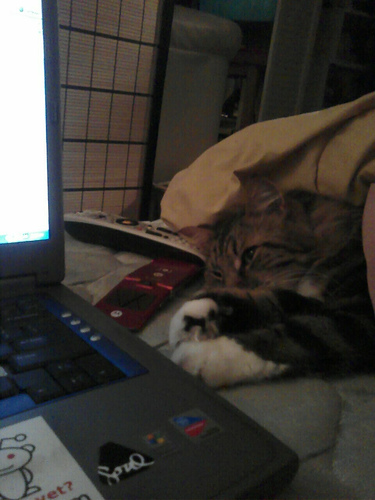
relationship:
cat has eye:
[167, 169, 373, 386] [240, 244, 257, 264]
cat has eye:
[167, 169, 373, 386] [210, 269, 222, 278]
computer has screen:
[0, 0, 298, 499] [5, 4, 51, 244]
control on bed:
[50, 190, 205, 275] [55, 193, 312, 468]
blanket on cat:
[160, 91, 374, 246] [189, 174, 358, 324]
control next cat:
[50, 190, 205, 275] [167, 169, 373, 386]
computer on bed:
[0, 0, 298, 499] [60, 219, 373, 498]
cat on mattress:
[167, 169, 373, 386] [57, 206, 371, 495]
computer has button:
[0, 0, 298, 499] [57, 308, 73, 319]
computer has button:
[0, 0, 298, 499] [17, 332, 60, 348]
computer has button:
[0, 0, 298, 499] [15, 346, 87, 359]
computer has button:
[0, 0, 298, 499] [50, 357, 76, 375]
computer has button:
[0, 0, 298, 499] [22, 318, 63, 336]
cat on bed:
[167, 169, 373, 386] [60, 219, 373, 498]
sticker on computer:
[167, 405, 223, 444] [1, 0, 298, 499]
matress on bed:
[65, 220, 356, 456] [65, 94, 374, 494]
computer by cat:
[1, 0, 298, 499] [167, 169, 373, 386]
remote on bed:
[63, 206, 212, 266] [60, 219, 373, 498]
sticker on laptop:
[167, 405, 223, 444] [27, 259, 253, 469]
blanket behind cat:
[160, 91, 374, 246] [167, 169, 373, 386]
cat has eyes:
[156, 149, 373, 386] [197, 231, 276, 285]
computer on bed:
[1, 0, 298, 499] [64, 191, 374, 495]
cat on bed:
[167, 169, 373, 386] [65, 94, 374, 494]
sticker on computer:
[1, 413, 106, 496] [0, 0, 298, 499]